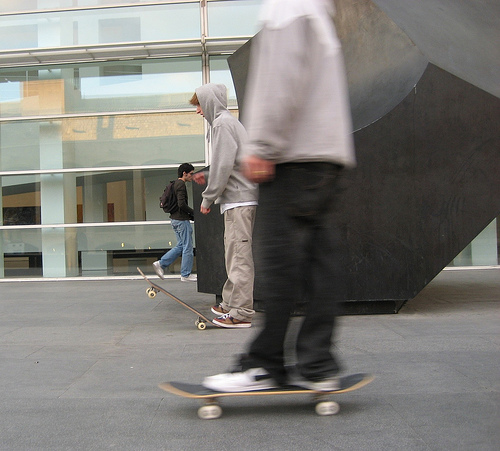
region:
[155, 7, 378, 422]
Skateboarder in motion on concrete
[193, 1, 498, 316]
Black sculpture on concrete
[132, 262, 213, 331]
Skateboard standing on end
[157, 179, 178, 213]
Backpack on walking man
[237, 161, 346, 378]
Black denim pants on skateboarder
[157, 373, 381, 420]
Sakteboard in motion on concrete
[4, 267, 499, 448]
Concrete surface in front of building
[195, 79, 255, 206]
Gray hooded sweatshirt on skateboarder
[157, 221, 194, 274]
Blue denim pants on pedestrian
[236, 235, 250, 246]
Pants manufacturer identification label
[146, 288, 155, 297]
Skate board wheels in the air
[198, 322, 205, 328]
Skate board wheel on the ground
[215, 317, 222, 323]
Foot on the skate board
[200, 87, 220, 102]
Hood covering the head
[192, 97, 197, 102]
Hair sticking out of the hood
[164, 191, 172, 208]
A black back pack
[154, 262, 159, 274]
Foot off the ground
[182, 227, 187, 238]
Person wearing jeans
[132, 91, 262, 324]
a boy stepping on the end of a skateboard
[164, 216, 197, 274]
a person wearing blue jeans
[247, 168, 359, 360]
a person wearing black pants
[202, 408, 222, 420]
a white skateboard wheel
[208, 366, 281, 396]
a white and black sneaker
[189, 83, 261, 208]
a boy wearing a grey sweatshirt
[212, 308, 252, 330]
a brown, black, and white skating shoe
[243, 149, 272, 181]
the hand of a person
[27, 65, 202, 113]
glass window on a building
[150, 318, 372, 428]
a person standing on a skateboard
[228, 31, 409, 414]
a manis on skateboards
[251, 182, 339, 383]
pants are black in color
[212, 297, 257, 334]
shoes are brown in color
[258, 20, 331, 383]
the man is blurred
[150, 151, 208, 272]
man walking in oposite doirection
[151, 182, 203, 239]
the man has a black bag at the back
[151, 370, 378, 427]
skateboard is black in color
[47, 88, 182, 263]
the building is beside the road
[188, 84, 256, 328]
A boy in a grey hooding over his head and khaki pants.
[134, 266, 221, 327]
Skateboard with black top and two wheels in the air.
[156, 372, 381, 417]
Black skateboard with white wheels on the ground and blurry.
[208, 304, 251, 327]
Brown, white and black sneakers on a boy.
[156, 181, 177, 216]
Black pack on a black haired guys back who is walking.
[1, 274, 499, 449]
Grey walkway people are on.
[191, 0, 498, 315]
A large black piece of art.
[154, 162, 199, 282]
A black haired guy in jeans walking with a backpack on.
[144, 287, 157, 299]
Two cream colored wheels off the ground.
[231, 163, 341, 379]
Black pants on a guy who is blurry.